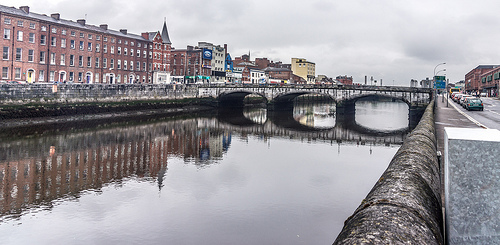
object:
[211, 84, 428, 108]
bridge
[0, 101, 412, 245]
water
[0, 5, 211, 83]
building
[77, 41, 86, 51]
windows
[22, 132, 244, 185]
reflection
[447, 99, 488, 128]
line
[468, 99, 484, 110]
cars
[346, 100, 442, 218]
pipe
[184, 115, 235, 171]
reflection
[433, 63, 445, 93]
street lights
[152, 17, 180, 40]
roof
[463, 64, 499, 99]
buildings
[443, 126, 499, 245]
slab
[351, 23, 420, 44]
cloud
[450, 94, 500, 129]
road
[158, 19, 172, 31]
steeple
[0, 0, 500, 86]
sky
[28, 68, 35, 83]
doorway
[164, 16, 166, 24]
top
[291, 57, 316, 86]
building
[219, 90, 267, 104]
opening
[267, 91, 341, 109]
opening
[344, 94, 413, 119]
opening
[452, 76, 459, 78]
right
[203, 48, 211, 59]
sign